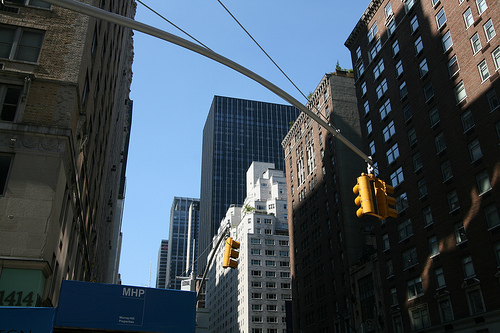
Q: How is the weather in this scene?
A: It is clear.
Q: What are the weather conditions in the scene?
A: It is clear.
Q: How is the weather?
A: It is clear.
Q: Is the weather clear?
A: Yes, it is clear.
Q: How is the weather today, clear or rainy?
A: It is clear.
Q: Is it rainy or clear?
A: It is clear.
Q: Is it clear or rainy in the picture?
A: It is clear.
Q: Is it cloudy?
A: No, it is clear.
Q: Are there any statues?
A: No, there are no statues.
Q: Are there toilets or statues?
A: No, there are no statues or toilets.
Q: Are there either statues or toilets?
A: No, there are no statues or toilets.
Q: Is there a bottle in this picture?
A: No, there are no bottles.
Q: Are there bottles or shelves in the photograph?
A: No, there are no bottles or shelves.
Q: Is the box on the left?
A: Yes, the box is on the left of the image.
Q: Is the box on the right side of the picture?
A: No, the box is on the left of the image.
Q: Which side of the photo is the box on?
A: The box is on the left of the image.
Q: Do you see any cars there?
A: No, there are no cars.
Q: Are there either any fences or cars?
A: No, there are no cars or fences.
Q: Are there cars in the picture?
A: No, there are no cars.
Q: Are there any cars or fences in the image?
A: No, there are no cars or fences.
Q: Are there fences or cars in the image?
A: No, there are no cars or fences.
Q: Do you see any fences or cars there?
A: No, there are no cars or fences.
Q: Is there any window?
A: Yes, there is a window.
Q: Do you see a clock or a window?
A: Yes, there is a window.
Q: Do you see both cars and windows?
A: No, there is a window but no cars.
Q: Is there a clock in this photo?
A: No, there are no clocks.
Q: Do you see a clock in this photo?
A: No, there are no clocks.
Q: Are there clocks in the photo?
A: No, there are no clocks.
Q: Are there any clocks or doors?
A: No, there are no clocks or doors.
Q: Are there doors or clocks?
A: No, there are no clocks or doors.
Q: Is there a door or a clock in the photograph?
A: No, there are no clocks or doors.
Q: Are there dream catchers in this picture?
A: No, there are no dream catchers.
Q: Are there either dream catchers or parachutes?
A: No, there are no dream catchers or parachutes.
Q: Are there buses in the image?
A: No, there are no buses.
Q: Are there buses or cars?
A: No, there are no buses or cars.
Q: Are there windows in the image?
A: Yes, there are windows.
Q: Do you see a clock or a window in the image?
A: Yes, there are windows.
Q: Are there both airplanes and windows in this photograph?
A: No, there are windows but no airplanes.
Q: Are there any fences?
A: No, there are no fences.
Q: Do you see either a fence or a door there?
A: No, there are no fences or doors.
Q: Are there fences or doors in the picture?
A: No, there are no fences or doors.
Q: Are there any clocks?
A: No, there are no clocks.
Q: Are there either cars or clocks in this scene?
A: No, there are no clocks or cars.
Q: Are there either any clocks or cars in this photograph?
A: No, there are no clocks or cars.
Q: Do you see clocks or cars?
A: No, there are no clocks or cars.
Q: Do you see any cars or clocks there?
A: No, there are no clocks or cars.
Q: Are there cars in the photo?
A: No, there are no cars.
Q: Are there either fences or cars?
A: No, there are no cars or fences.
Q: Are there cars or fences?
A: No, there are no cars or fences.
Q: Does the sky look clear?
A: Yes, the sky is clear.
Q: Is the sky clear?
A: Yes, the sky is clear.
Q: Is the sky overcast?
A: No, the sky is clear.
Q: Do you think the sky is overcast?
A: No, the sky is clear.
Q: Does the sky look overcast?
A: No, the sky is clear.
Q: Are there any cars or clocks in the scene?
A: No, there are no clocks or cars.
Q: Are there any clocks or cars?
A: No, there are no clocks or cars.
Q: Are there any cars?
A: No, there are no cars.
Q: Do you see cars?
A: No, there are no cars.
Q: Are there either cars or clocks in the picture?
A: No, there are no cars or clocks.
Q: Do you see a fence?
A: No, there are no fences.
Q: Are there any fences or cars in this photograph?
A: No, there are no fences or cars.